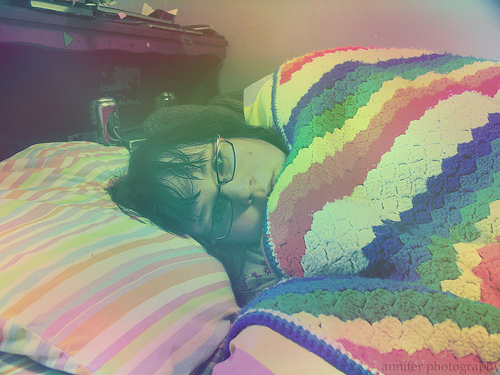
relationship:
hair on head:
[103, 98, 287, 270] [99, 101, 299, 262]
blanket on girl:
[219, 39, 498, 373] [105, 89, 325, 311]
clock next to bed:
[119, 128, 164, 157] [2, 0, 497, 374]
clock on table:
[119, 128, 164, 157] [0, 0, 227, 148]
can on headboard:
[52, 72, 130, 142] [0, 1, 228, 152]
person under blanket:
[117, 95, 500, 293] [243, 46, 498, 373]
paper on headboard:
[79, 99, 139, 154] [0, 1, 228, 152]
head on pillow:
[134, 113, 295, 233] [3, 118, 255, 368]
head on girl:
[134, 113, 295, 233] [133, 96, 329, 329]